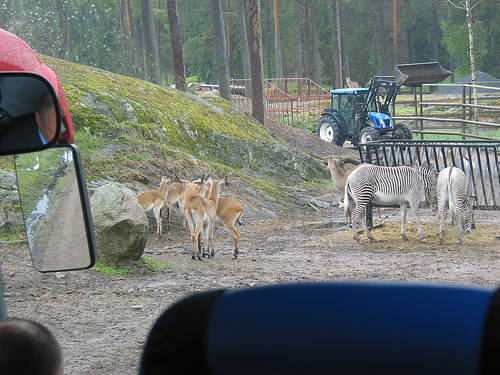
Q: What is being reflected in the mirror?
A: The view from behind the vehicle.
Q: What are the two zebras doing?
A: Looking at the ground.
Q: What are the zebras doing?
A: Eating hay.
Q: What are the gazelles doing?
A: Standing close together.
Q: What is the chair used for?
A: Passengers in the vehicle.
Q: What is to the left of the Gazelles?
A: A large grey boulder.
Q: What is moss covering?
A: Large rock on left.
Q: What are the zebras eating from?
A: A black metal feeder.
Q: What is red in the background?
A: A metal enclosure.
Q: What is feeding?
A: Two zebras.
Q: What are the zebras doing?
A: Feeding.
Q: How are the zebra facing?
A: Away from the camera.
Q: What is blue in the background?
A: Tractor.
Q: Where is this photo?
A: Zoo.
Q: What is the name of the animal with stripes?
A: Zebra.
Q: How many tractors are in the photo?
A: One.